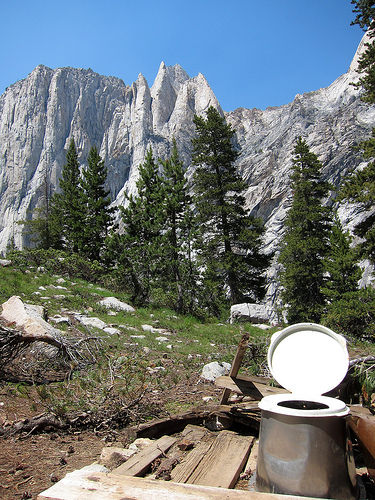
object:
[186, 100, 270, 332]
pine tree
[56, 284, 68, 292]
rocks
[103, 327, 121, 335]
rocks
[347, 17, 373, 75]
mountain peek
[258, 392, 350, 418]
seat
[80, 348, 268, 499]
trash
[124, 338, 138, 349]
rocks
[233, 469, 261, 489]
water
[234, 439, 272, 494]
wood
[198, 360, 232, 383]
rock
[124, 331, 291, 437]
wood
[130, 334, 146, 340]
rock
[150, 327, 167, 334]
rock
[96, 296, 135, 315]
rock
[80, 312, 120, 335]
rock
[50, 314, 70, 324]
rock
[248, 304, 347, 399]
cover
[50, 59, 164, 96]
top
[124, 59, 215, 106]
mountain tips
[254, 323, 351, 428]
toilet seat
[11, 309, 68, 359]
rocks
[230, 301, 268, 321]
rock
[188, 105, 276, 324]
trees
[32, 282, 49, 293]
white rock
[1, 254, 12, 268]
white rock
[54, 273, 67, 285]
white rock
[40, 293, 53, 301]
white rock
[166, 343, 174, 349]
rocks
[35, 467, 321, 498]
board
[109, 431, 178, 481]
board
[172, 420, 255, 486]
board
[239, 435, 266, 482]
board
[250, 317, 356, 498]
pot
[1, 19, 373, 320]
mountain range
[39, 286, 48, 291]
rocks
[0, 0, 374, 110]
sky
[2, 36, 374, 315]
mountain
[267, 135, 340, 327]
pine tree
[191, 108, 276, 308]
pine tree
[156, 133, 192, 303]
pine tree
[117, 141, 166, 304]
pine tree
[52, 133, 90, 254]
pine tree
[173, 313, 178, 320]
rocks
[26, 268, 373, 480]
ground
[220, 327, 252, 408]
wood piece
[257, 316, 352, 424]
toilet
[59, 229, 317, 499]
field